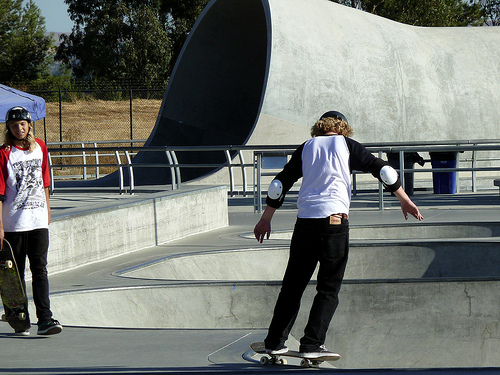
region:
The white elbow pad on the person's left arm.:
[261, 170, 286, 207]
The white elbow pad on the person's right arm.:
[373, 159, 403, 187]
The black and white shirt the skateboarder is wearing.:
[274, 136, 401, 205]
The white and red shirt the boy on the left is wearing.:
[2, 142, 54, 237]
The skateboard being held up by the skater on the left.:
[0, 237, 39, 347]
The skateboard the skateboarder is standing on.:
[241, 337, 348, 374]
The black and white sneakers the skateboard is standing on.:
[266, 331, 341, 363]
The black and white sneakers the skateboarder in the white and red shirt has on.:
[13, 310, 65, 337]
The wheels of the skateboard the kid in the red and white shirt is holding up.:
[1, 252, 33, 329]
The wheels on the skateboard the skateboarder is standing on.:
[251, 350, 318, 371]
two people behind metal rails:
[388, 128, 466, 195]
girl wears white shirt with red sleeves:
[1, 104, 66, 231]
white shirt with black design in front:
[8, 154, 66, 238]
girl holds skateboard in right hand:
[0, 101, 71, 336]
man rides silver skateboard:
[238, 107, 427, 366]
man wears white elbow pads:
[258, 162, 418, 197]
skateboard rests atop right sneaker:
[5, 220, 37, 337]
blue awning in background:
[0, 76, 49, 123]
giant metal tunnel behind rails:
[108, 0, 498, 187]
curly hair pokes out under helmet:
[311, 110, 353, 137]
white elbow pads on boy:
[264, 170, 414, 198]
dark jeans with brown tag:
[301, 213, 343, 357]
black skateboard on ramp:
[239, 333, 351, 366]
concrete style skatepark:
[108, 206, 455, 341]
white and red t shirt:
[0, 149, 68, 237]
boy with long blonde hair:
[8, 102, 55, 162]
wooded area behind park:
[5, 13, 187, 102]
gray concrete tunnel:
[158, 51, 409, 123]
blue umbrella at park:
[5, 74, 62, 126]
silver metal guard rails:
[63, 123, 492, 173]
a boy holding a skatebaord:
[0, 97, 77, 353]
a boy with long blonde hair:
[0, 104, 47, 161]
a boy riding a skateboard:
[243, 96, 412, 368]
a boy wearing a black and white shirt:
[265, 86, 387, 256]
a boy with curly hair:
[306, 92, 378, 147]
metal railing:
[93, 127, 264, 208]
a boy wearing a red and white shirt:
[1, 90, 72, 240]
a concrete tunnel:
[64, 15, 431, 202]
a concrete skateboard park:
[68, 181, 473, 334]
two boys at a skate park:
[0, 96, 425, 327]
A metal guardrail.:
[37, 133, 493, 218]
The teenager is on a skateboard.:
[225, 102, 430, 367]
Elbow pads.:
[255, 150, 416, 201]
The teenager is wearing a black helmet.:
[0, 95, 35, 160]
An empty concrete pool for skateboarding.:
[40, 240, 490, 365]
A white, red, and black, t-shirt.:
[0, 135, 60, 225]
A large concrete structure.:
[145, 0, 495, 140]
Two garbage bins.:
[380, 135, 465, 195]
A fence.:
[30, 80, 155, 160]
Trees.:
[10, 10, 175, 95]